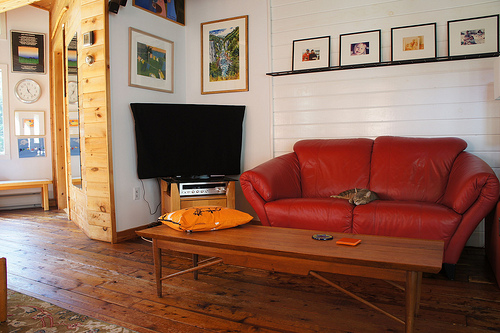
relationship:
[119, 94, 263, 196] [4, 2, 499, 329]
tv in a house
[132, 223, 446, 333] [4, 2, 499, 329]
wood table in a house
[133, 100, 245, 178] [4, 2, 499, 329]
tv screen in a house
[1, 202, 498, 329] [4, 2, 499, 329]
floor in a house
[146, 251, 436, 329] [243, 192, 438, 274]
legs on a table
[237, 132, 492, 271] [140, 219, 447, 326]
couch near a table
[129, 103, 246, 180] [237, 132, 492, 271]
tv near a couch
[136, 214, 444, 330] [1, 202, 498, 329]
wood table on floor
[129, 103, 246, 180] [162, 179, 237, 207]
tv on table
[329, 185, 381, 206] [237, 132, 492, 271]
cat sitting on couch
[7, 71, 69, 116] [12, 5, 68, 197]
clock on wall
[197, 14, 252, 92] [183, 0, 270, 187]
picture hanging on wall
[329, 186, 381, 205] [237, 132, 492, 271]
cat lying on couch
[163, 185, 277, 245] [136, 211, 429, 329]
pillow on table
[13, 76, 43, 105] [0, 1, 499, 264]
clock hanging on wall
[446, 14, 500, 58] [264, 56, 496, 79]
picture sitting on shelf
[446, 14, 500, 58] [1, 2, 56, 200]
picture hanging on wall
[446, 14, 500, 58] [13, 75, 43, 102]
picture hanging above clock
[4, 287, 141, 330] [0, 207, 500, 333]
carpet on floor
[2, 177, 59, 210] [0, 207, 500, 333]
bench on floor